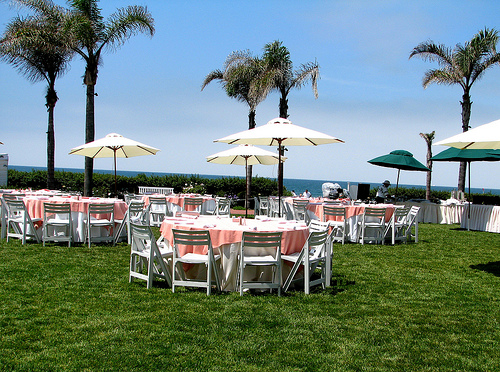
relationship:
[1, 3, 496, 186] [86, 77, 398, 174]
sky has clouds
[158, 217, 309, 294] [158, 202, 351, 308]
table on table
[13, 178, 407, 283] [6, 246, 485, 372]
tables on grass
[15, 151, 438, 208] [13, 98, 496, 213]
water in background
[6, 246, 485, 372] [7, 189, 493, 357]
grass on ground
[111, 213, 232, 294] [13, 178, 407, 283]
chairs next to tables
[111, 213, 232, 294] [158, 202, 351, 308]
chairs next to table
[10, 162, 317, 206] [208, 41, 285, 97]
hedge next to palm tree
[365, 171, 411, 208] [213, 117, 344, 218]
man under parsol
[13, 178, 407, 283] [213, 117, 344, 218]
tables have parsol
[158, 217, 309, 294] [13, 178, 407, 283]
table on tables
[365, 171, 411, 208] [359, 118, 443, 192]
man under parasol